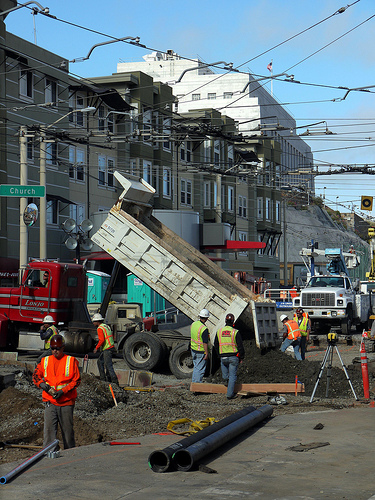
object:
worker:
[189, 308, 209, 394]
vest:
[189, 320, 209, 351]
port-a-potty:
[86, 270, 109, 305]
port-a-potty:
[125, 272, 165, 323]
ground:
[1, 406, 373, 498]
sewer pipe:
[148, 406, 256, 472]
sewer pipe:
[172, 404, 274, 472]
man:
[33, 333, 80, 452]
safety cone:
[347, 337, 370, 373]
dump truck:
[0, 170, 282, 378]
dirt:
[215, 337, 375, 398]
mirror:
[23, 202, 38, 226]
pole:
[19, 125, 28, 275]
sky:
[3, 0, 375, 218]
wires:
[177, 0, 359, 101]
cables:
[16, 3, 348, 91]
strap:
[166, 416, 217, 438]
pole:
[360, 349, 369, 400]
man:
[33, 316, 59, 368]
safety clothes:
[31, 353, 82, 407]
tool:
[102, 439, 141, 447]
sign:
[0, 183, 46, 199]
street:
[0, 329, 375, 500]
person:
[212, 313, 247, 399]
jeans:
[220, 356, 240, 398]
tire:
[123, 331, 163, 371]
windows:
[76, 164, 85, 179]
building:
[0, 0, 282, 291]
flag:
[266, 62, 272, 98]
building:
[117, 48, 314, 194]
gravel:
[14, 363, 350, 432]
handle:
[107, 439, 143, 443]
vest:
[42, 354, 73, 394]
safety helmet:
[199, 306, 211, 321]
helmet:
[50, 332, 67, 350]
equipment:
[308, 332, 358, 406]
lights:
[65, 235, 79, 251]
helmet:
[198, 308, 210, 319]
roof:
[178, 94, 259, 108]